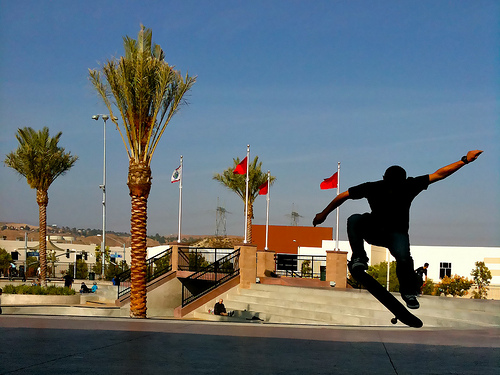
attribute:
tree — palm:
[86, 17, 198, 317]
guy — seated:
[210, 296, 230, 320]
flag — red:
[316, 168, 341, 192]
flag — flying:
[232, 155, 251, 179]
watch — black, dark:
[458, 155, 470, 166]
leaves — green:
[89, 67, 120, 121]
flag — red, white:
[254, 178, 271, 199]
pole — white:
[335, 159, 342, 247]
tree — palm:
[6, 123, 83, 286]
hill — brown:
[6, 221, 253, 247]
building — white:
[418, 240, 498, 287]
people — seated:
[80, 270, 124, 296]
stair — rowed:
[198, 275, 498, 331]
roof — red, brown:
[250, 223, 333, 254]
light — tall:
[88, 110, 125, 279]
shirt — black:
[211, 302, 228, 317]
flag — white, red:
[167, 163, 183, 184]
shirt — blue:
[90, 283, 100, 292]